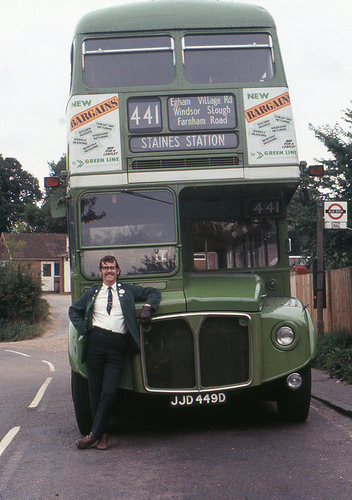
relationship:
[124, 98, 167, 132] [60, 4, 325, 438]
number on bus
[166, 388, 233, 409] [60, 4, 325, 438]
license plate on bus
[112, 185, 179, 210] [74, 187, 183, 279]
wiper on windshield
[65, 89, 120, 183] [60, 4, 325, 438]
advertising on bus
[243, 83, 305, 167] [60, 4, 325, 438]
advertising on bus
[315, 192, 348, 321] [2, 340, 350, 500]
sign by road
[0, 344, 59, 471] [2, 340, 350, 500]
lines on road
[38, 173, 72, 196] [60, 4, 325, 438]
turn signal on bus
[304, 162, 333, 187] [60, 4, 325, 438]
turn signal on bus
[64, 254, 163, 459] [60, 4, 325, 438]
driver leaning on bus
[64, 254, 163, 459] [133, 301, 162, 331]
driver wearing glove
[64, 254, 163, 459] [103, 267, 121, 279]
driver has mustache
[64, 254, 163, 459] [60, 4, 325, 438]
driver leans on bus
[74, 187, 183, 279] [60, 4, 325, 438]
windshield of bus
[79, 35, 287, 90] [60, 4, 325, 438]
windshield on bus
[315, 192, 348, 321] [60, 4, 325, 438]
sign by bus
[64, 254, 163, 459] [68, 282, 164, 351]
driver wears jacket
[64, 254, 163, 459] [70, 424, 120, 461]
driver has feet crossed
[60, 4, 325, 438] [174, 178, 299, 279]
bus has no window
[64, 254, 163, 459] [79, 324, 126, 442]
driver has pants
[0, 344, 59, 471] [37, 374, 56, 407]
lines have edge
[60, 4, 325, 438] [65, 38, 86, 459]
bus has edge